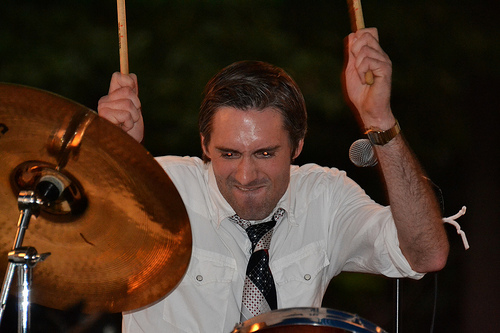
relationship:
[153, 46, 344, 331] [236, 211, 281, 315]
man with necktie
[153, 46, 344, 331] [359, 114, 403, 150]
man wearing watch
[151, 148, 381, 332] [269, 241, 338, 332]
shirt has pocket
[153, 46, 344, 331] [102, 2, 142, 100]
man holding drumstick